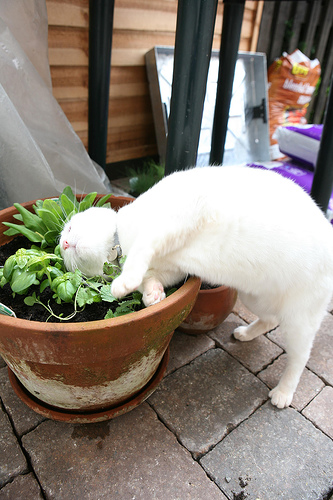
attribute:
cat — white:
[56, 153, 323, 410]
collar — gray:
[105, 208, 132, 263]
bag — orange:
[263, 47, 322, 173]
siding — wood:
[1, 0, 277, 175]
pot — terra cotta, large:
[1, 186, 205, 429]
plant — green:
[1, 185, 183, 329]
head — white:
[35, 212, 114, 281]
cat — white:
[58, 165, 292, 289]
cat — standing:
[40, 182, 328, 304]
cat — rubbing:
[48, 167, 319, 309]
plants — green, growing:
[10, 188, 185, 353]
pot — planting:
[12, 192, 173, 436]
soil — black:
[31, 290, 110, 337]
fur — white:
[105, 189, 297, 304]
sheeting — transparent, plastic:
[2, 10, 124, 226]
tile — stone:
[147, 368, 314, 484]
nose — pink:
[45, 230, 80, 252]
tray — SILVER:
[157, 96, 293, 161]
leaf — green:
[21, 211, 37, 228]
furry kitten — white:
[49, 150, 320, 387]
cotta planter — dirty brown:
[6, 181, 207, 441]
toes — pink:
[145, 289, 160, 301]